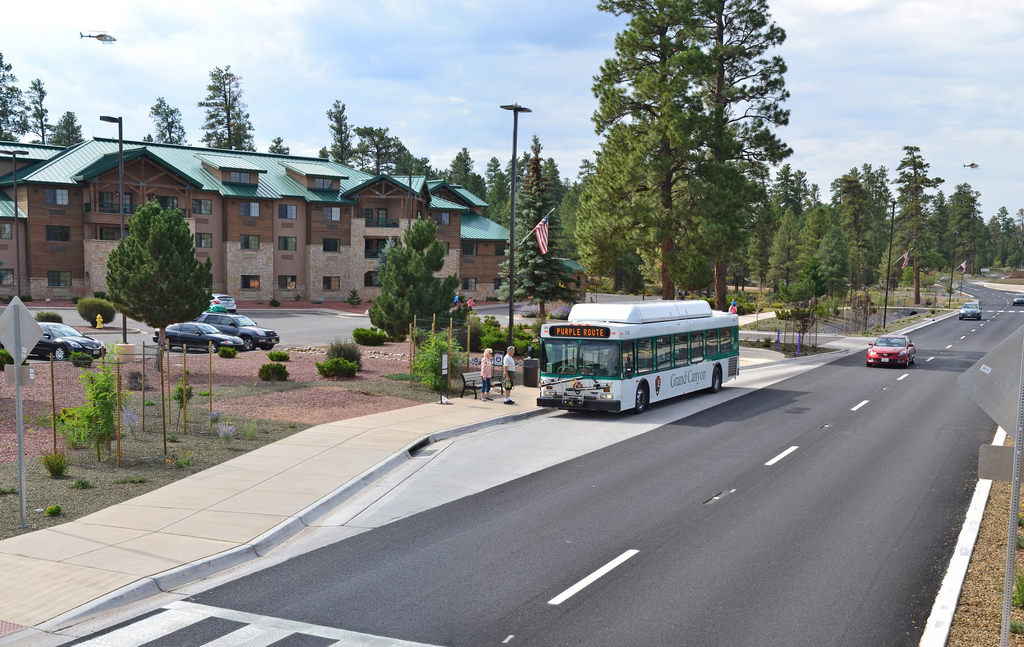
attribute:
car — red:
[860, 329, 919, 369]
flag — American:
[523, 209, 555, 254]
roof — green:
[27, 126, 111, 185]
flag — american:
[506, 202, 564, 256]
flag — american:
[506, 207, 548, 258]